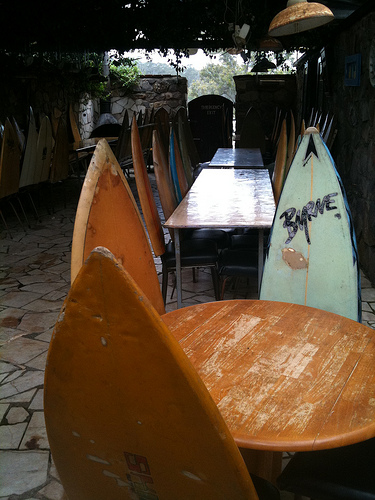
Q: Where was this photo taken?
A: In a restaurant.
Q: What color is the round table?
A: Brown.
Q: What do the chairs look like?
A: Surfboards.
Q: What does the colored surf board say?
A: Byrne.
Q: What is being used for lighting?
A: Coconuts.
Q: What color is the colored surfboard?
A: Light blue.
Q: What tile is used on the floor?
A: Ceramic.